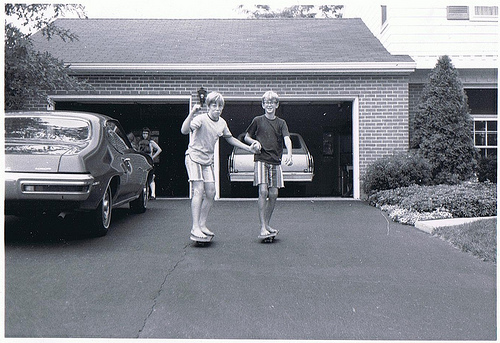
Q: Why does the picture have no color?
A: It's black and white.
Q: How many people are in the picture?
A: Three.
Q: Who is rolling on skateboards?
A: Two boys.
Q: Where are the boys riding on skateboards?
A: In the driveway.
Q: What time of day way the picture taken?
A: During the day.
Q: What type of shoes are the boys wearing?
A: None.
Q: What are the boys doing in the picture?
A: Skateboarding.